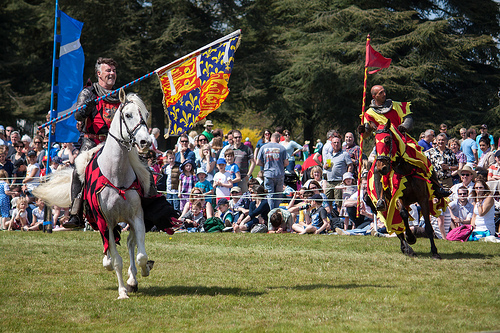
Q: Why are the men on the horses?
A: Riding.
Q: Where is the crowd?
A: Behind the men.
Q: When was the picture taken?
A: DAytime.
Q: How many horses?
A: 2.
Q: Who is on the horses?
A: Men.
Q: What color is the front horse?
A: White.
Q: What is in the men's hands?
A: Flags.